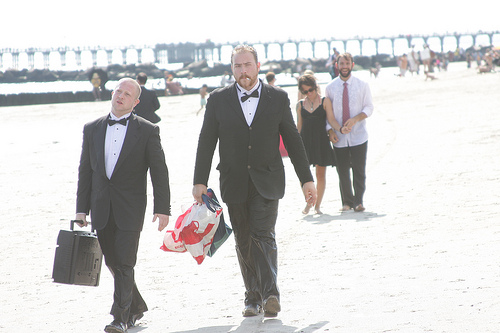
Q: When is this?
A: Daytime.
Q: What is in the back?
A: Bridge.